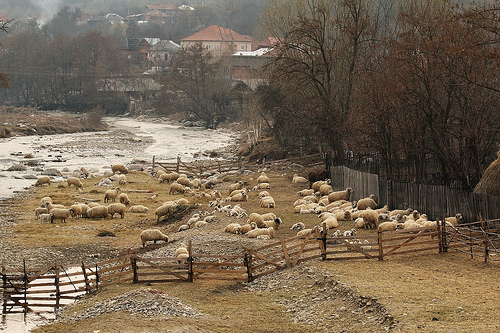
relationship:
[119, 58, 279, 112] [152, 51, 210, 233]
buildings behind fence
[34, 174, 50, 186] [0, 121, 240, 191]
lamb beside water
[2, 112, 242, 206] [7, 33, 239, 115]
river along woods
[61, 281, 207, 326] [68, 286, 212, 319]
pile of rocks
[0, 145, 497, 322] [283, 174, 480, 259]
pen full of sheep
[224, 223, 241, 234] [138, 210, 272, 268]
sheep on rocks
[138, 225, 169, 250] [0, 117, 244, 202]
sheep drinking water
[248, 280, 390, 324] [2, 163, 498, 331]
rocks on ground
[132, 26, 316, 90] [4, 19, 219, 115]
houses covered by trees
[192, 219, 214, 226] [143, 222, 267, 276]
lamb on rocks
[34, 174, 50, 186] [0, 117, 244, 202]
lamb drinking water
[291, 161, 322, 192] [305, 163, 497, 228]
horse by fence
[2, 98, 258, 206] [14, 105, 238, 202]
river has water